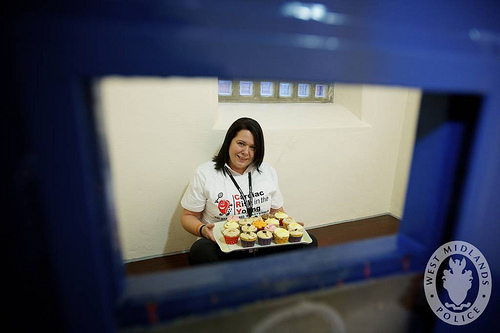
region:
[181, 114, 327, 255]
A woman holding a tray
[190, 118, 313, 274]
A woman holding a tray of cupcakes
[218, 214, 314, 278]
Cupcakes on a tray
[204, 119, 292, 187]
A woman with black hair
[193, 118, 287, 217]
A woman wearing a white tee shirt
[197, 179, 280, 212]
A white tee shirt with letters on it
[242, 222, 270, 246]
Three cupcakes on a tray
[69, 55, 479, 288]
A woman in a blue window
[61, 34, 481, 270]
A blue window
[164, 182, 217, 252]
The arm of a woman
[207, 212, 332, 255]
the cupcakes are on a tray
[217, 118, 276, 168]
her hair is black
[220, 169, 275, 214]
the shirt is white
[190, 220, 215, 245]
she has a black and orange band on her wrist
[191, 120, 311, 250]
the woman is squtting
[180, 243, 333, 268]
the pants are black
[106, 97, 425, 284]
the room is a cell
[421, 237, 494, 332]
the sign says west midlands police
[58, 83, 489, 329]
the door has a glass to see through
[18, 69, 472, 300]
the scene is an indoor scene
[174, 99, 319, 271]
Woman holding a tray of cupcakes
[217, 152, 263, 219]
Lanyard hanging from the woman's neck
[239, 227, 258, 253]
Cupcake with a purple cupcake liner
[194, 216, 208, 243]
Bracelets on the woman's right wrist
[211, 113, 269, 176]
Woman with black hair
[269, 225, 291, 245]
Cupcake with a yellow cupcake liner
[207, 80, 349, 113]
Window with bars on it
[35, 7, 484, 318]
View inside a jail cell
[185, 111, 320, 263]
Woman wearing a white shirt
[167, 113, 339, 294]
Woman wearing black pants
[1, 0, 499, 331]
A rectangular window through the top of a blue door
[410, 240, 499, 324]
A white circle with the words West Midlands Police with a logo in the center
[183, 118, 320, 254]
Woman sitting down in a room with a tray of cupcakes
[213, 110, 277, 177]
A woman smiling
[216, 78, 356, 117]
A paned window in the room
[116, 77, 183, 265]
Part of a white painted wall in the room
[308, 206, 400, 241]
Part of a brown seat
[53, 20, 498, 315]
The edge of the window in the door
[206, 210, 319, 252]
Woman holding a tray of cupcakes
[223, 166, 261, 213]
A black lanyard around the woman's neck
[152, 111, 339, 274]
a woman holding a tray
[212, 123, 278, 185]
a woman with brown hair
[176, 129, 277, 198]
a woman smiling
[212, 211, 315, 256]
several cupcakes on a tray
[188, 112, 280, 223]
a woman wearing a white shirt with black letters on it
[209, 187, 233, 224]
a red design of a heart on a white shirt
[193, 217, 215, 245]
two bands on a woman's wrist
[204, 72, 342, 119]
a small row of windows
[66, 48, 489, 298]
a glass window with blue trim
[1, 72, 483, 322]
a blue wall with a window